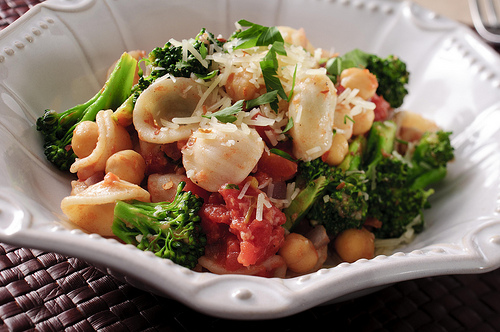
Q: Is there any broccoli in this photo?
A: Yes, there is broccoli.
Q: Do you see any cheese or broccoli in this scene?
A: Yes, there is broccoli.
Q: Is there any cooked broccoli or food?
A: Yes, there is cooked broccoli.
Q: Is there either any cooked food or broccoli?
A: Yes, there is cooked broccoli.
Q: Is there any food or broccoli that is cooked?
A: Yes, the broccoli is cooked.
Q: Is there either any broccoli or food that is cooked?
A: Yes, the broccoli is cooked.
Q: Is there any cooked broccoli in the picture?
A: Yes, there is cooked broccoli.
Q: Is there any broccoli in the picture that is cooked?
A: Yes, there is broccoli that is cooked.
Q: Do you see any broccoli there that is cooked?
A: Yes, there is broccoli that is cooked.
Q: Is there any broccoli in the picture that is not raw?
A: Yes, there is cooked broccoli.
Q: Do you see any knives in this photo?
A: No, there are no knives.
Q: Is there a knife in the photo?
A: No, there are no knives.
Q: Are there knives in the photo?
A: No, there are no knives.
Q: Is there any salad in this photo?
A: Yes, there is salad.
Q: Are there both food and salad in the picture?
A: Yes, there are both salad and food.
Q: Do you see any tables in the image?
A: Yes, there is a table.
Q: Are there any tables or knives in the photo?
A: Yes, there is a table.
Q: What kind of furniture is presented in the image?
A: The furniture is a table.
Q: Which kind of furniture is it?
A: The piece of furniture is a table.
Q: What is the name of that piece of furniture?
A: That is a table.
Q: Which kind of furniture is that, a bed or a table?
A: That is a table.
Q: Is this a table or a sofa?
A: This is a table.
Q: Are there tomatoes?
A: Yes, there are tomatoes.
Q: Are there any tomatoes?
A: Yes, there are tomatoes.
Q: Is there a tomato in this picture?
A: Yes, there are tomatoes.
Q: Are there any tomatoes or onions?
A: Yes, there are tomatoes.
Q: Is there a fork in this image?
A: No, there are no forks.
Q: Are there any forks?
A: No, there are no forks.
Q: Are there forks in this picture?
A: No, there are no forks.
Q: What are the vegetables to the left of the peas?
A: The vegetables are tomatoes.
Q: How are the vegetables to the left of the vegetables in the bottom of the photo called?
A: The vegetables are tomatoes.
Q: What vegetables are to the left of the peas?
A: The vegetables are tomatoes.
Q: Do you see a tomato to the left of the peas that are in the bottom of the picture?
A: Yes, there are tomatoes to the left of the peas.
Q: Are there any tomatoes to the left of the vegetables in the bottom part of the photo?
A: Yes, there are tomatoes to the left of the peas.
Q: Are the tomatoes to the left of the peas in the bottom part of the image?
A: Yes, the tomatoes are to the left of the peas.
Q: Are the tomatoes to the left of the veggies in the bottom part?
A: Yes, the tomatoes are to the left of the peas.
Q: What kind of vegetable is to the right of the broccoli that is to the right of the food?
A: The vegetables are tomatoes.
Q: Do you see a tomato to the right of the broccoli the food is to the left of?
A: Yes, there are tomatoes to the right of the broccoli.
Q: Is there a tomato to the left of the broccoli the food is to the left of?
A: No, the tomatoes are to the right of the broccoli.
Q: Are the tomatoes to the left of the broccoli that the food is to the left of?
A: No, the tomatoes are to the right of the broccoli.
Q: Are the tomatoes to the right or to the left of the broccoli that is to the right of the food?
A: The tomatoes are to the right of the broccoli.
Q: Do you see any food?
A: Yes, there is food.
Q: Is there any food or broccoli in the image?
A: Yes, there is food.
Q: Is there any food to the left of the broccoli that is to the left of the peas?
A: Yes, there is food to the left of the broccoli.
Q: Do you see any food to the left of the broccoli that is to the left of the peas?
A: Yes, there is food to the left of the broccoli.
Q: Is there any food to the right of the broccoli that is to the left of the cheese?
A: No, the food is to the left of the broccoli.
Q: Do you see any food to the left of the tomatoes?
A: Yes, there is food to the left of the tomatoes.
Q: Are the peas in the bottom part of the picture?
A: Yes, the peas are in the bottom of the image.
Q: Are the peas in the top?
A: No, the peas are in the bottom of the image.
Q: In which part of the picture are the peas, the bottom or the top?
A: The peas are in the bottom of the image.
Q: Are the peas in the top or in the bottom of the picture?
A: The peas are in the bottom of the image.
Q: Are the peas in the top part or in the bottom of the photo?
A: The peas are in the bottom of the image.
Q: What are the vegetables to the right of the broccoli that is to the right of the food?
A: The vegetables are peas.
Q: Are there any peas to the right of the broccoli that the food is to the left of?
A: Yes, there are peas to the right of the broccoli.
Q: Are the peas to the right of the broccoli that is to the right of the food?
A: Yes, the peas are to the right of the broccoli.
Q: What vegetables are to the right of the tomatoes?
A: The vegetables are peas.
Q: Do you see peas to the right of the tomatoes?
A: Yes, there are peas to the right of the tomatoes.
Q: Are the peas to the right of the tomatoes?
A: Yes, the peas are to the right of the tomatoes.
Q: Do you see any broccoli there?
A: Yes, there is broccoli.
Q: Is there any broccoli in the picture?
A: Yes, there is broccoli.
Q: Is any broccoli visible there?
A: Yes, there is broccoli.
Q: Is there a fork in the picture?
A: No, there are no forks.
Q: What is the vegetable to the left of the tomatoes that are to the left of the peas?
A: The vegetable is broccoli.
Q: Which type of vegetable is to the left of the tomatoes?
A: The vegetable is broccoli.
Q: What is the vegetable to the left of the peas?
A: The vegetable is broccoli.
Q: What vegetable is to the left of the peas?
A: The vegetable is broccoli.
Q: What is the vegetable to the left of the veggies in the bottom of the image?
A: The vegetable is broccoli.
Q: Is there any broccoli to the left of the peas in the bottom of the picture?
A: Yes, there is broccoli to the left of the peas.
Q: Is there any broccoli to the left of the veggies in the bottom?
A: Yes, there is broccoli to the left of the peas.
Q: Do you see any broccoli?
A: Yes, there is broccoli.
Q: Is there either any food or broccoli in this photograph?
A: Yes, there is broccoli.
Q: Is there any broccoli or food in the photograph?
A: Yes, there is broccoli.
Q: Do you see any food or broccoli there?
A: Yes, there is broccoli.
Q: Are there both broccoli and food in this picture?
A: Yes, there are both broccoli and food.